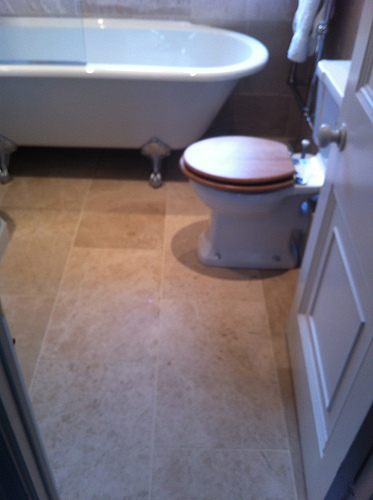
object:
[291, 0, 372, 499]
silver door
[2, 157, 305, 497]
marbled floor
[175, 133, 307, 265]
toilet seat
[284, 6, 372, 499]
panel on door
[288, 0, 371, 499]
door is white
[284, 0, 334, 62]
towel is white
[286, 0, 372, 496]
door frame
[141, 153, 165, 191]
silver leg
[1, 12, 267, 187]
white tub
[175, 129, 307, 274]
toilet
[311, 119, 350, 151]
white door knob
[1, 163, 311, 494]
colored floor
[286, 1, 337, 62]
white towel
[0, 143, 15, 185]
silver leg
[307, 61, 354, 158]
white toilet tank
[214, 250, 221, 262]
bolt on toilet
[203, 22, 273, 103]
edge of the tub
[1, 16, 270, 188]
claw foot bathtub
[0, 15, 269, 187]
bathtub is white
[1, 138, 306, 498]
tile floor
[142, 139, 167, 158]
metal claw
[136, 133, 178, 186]
claw foot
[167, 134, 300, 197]
wooden toilet seat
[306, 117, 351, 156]
silver door knob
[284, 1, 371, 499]
bathroom door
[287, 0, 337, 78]
towel on rack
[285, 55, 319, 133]
silver pipe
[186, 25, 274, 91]
white edge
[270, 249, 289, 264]
large bolt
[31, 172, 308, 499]
tan lines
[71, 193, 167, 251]
artisan tile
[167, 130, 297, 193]
wood base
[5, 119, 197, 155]
white base on tub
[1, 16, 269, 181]
shiny bath tub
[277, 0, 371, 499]
grooves in door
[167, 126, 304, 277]
wooden seat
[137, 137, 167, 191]
lion foot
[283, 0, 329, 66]
cotton towel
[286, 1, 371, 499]
door with knob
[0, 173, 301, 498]
ceramic floor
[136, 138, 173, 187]
silver lion foot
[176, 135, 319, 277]
toilet is white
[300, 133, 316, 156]
toilet plunger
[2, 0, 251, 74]
shower curtain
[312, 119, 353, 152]
metal door knob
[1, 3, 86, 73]
spray shield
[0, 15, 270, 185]
tub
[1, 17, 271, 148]
bathtub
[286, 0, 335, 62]
towel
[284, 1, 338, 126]
rack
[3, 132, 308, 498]
floor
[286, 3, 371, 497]
door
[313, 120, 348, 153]
door knob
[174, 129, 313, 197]
seat